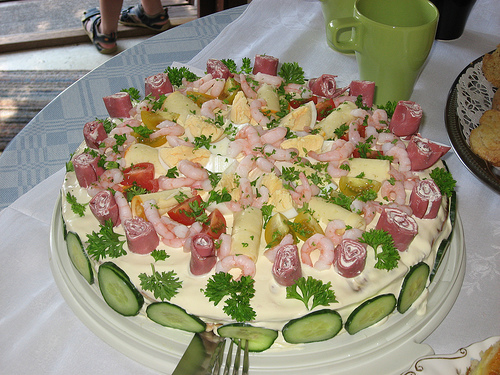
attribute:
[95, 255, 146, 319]
cucumber — green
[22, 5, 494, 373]
tablecloth — white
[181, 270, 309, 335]
leaves — parsley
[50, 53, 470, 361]
cake — yellow, white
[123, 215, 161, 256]
meat — rolled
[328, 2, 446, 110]
coffee cup — lime green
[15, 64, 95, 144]
rug — striped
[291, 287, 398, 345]
cucumbers — thinly sliced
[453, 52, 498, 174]
doily — white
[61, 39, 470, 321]
ham slices — rolled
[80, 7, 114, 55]
sandals — black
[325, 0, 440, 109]
cup — green, light green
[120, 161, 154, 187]
tomato — grape, wedge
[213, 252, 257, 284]
peeled shrimp — cold, cooked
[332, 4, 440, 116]
mug — green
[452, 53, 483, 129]
doily — white